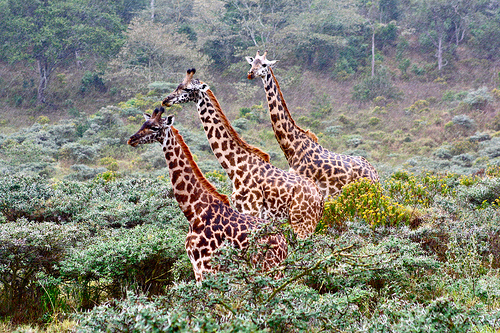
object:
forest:
[0, 0, 497, 83]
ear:
[270, 60, 280, 68]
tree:
[362, 17, 384, 78]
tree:
[414, 2, 456, 74]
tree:
[0, 1, 126, 104]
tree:
[101, 16, 215, 97]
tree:
[182, 0, 237, 63]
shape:
[212, 224, 224, 231]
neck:
[258, 73, 317, 148]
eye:
[181, 88, 191, 92]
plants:
[0, 168, 185, 328]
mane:
[268, 67, 318, 144]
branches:
[375, 21, 400, 40]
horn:
[262, 49, 268, 57]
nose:
[248, 71, 253, 74]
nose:
[165, 96, 170, 100]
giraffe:
[126, 107, 288, 293]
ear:
[164, 114, 175, 127]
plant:
[442, 114, 478, 138]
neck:
[162, 124, 213, 222]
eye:
[261, 63, 267, 67]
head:
[161, 68, 199, 108]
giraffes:
[244, 49, 380, 202]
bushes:
[76, 167, 499, 333]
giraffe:
[162, 68, 325, 240]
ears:
[143, 113, 151, 121]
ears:
[201, 83, 209, 90]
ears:
[245, 56, 254, 65]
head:
[127, 106, 174, 147]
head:
[245, 49, 280, 79]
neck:
[198, 79, 248, 173]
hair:
[170, 125, 230, 206]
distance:
[82, 51, 442, 219]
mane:
[207, 89, 270, 164]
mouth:
[127, 140, 140, 147]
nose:
[130, 135, 137, 139]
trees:
[463, 87, 495, 114]